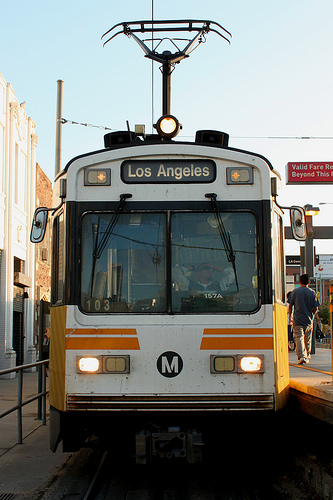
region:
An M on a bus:
[150, 342, 191, 388]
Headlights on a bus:
[209, 350, 271, 391]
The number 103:
[79, 291, 119, 315]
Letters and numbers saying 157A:
[194, 287, 232, 303]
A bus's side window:
[281, 200, 311, 248]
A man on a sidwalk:
[287, 263, 323, 368]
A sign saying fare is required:
[288, 151, 332, 190]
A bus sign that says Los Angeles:
[115, 152, 225, 194]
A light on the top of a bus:
[148, 108, 191, 137]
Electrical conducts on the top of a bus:
[90, 13, 238, 83]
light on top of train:
[144, 107, 186, 151]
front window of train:
[66, 200, 264, 325]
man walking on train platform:
[284, 270, 331, 390]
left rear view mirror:
[269, 176, 310, 244]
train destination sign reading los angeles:
[115, 159, 224, 185]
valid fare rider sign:
[283, 159, 332, 187]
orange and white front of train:
[64, 305, 276, 391]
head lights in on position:
[73, 348, 269, 380]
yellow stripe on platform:
[298, 362, 331, 413]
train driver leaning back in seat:
[170, 258, 238, 313]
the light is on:
[66, 352, 266, 388]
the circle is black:
[154, 352, 191, 382]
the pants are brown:
[292, 326, 318, 359]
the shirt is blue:
[290, 283, 319, 320]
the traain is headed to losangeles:
[117, 159, 216, 180]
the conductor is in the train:
[176, 259, 240, 295]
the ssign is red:
[291, 165, 332, 184]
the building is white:
[1, 97, 32, 256]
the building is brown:
[38, 170, 53, 282]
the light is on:
[305, 203, 323, 216]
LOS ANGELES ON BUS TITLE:
[125, 153, 217, 187]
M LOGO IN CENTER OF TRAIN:
[156, 350, 186, 383]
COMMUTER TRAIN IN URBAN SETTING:
[71, 163, 266, 368]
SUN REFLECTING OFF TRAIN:
[274, 294, 317, 380]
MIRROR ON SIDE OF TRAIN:
[36, 201, 52, 248]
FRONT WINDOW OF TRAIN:
[83, 211, 250, 307]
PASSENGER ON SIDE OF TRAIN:
[292, 271, 314, 360]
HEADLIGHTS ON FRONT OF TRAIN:
[74, 352, 267, 371]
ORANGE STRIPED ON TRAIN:
[65, 326, 268, 350]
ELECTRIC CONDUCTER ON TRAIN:
[107, 22, 224, 56]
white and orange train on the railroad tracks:
[29, 115, 306, 498]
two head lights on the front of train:
[76, 353, 265, 372]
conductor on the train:
[171, 260, 234, 309]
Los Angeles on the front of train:
[29, 115, 307, 497]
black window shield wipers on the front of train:
[77, 191, 254, 288]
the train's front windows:
[76, 207, 261, 312]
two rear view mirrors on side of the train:
[29, 205, 308, 243]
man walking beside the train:
[286, 273, 320, 365]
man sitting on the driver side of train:
[170, 263, 235, 309]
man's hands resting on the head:
[170, 263, 235, 285]